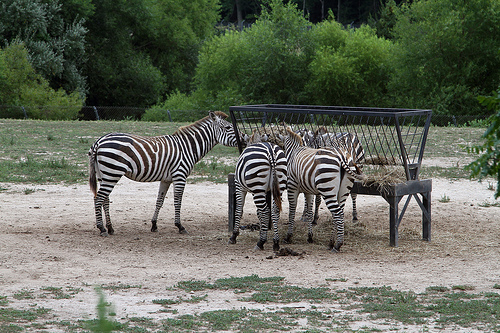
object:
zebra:
[78, 109, 252, 240]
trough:
[227, 99, 439, 258]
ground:
[3, 238, 219, 296]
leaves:
[458, 84, 499, 199]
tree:
[0, 38, 90, 122]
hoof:
[104, 223, 116, 236]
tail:
[84, 143, 101, 200]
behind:
[90, 130, 120, 180]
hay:
[247, 125, 297, 144]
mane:
[170, 104, 230, 133]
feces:
[266, 244, 305, 264]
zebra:
[272, 124, 373, 252]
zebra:
[227, 128, 292, 255]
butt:
[243, 145, 291, 196]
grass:
[168, 276, 215, 295]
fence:
[72, 102, 152, 122]